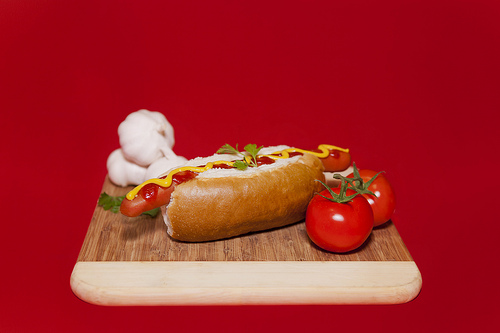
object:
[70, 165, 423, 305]
cutting board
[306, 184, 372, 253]
tomatoes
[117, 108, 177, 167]
garlic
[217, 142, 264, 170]
parsely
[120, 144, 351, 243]
hot dog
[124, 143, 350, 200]
mustard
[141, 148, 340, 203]
ketchup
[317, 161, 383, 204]
stems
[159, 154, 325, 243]
bun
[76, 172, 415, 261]
wood grain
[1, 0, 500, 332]
background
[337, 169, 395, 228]
food